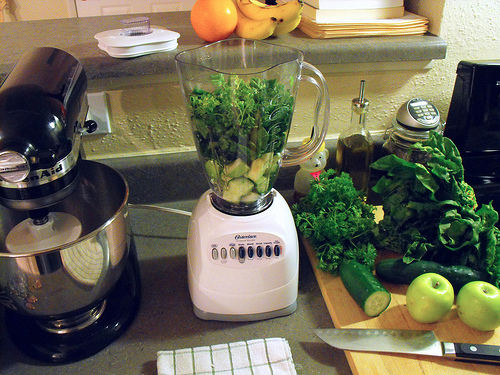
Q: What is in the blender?
A: Vegetables and fruit.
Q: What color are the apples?
A: Green.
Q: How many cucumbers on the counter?
A: One.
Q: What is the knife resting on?
A: Cutting board.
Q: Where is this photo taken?
A: Kitchen.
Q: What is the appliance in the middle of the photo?
A: Blender.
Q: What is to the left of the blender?
A: A standing mixer.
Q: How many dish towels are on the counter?
A: One.